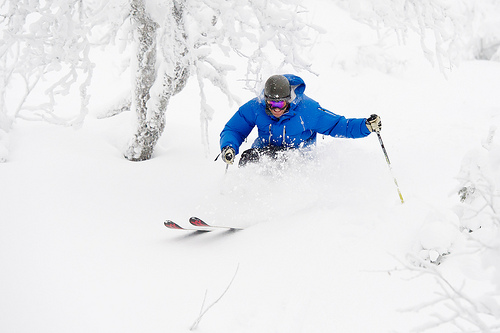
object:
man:
[219, 74, 382, 168]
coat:
[219, 73, 371, 151]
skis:
[161, 219, 218, 229]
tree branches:
[30, 0, 92, 103]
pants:
[239, 142, 294, 166]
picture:
[2, 2, 499, 332]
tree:
[5, 4, 94, 127]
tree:
[120, 0, 201, 162]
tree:
[396, 3, 448, 73]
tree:
[469, 7, 499, 58]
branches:
[389, 252, 498, 331]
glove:
[364, 114, 383, 133]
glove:
[220, 146, 236, 163]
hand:
[367, 114, 382, 132]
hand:
[220, 148, 237, 164]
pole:
[364, 114, 405, 205]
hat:
[264, 75, 290, 99]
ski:
[187, 217, 242, 231]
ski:
[164, 218, 206, 231]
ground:
[2, 60, 499, 330]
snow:
[0, 11, 498, 331]